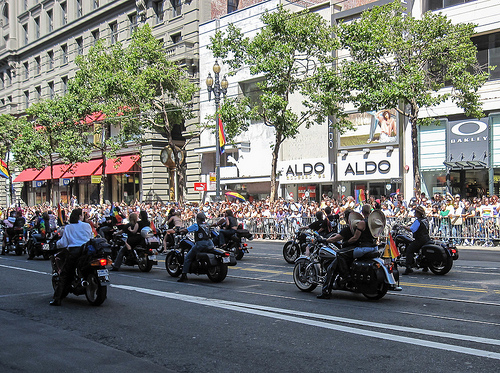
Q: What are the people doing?
A: Riding motorcycles.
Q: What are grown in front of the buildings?
A: Trees.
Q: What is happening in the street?
A: A parade of motorcycles.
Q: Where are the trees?
A: In front of the buildings.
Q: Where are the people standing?
A: On the roadside.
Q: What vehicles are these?
A: Motorcycles.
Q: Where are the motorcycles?
A: On the road.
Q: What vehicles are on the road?
A: Motorcycles.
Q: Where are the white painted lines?
A: On the road.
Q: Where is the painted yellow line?
A: Middle of road.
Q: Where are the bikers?
A: On the motorcycles.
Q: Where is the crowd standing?
A: Behind the fence.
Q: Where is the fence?
A: In front of the crowd.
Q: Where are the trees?
A: By the buildings.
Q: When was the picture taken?
A: During a motorcycle parade.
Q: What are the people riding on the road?
A: Motorcycles.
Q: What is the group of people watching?
A: Spectators.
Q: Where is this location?
A: Downtown.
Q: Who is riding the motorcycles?
A: Bikers.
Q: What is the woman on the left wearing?
A: White.